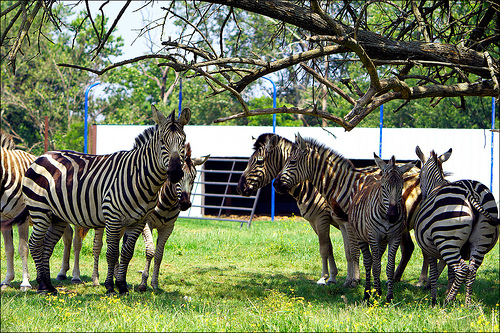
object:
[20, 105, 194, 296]
zebra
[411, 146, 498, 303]
zebra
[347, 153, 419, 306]
zebra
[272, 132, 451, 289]
zebra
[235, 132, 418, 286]
zebra